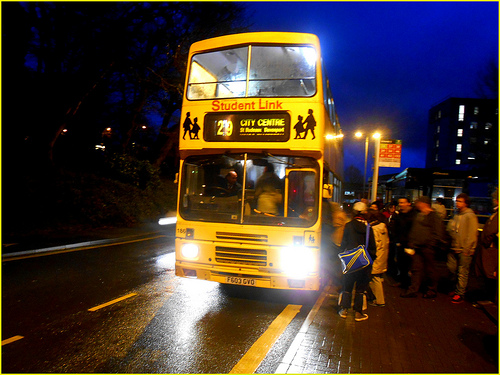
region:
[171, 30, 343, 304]
yellow double decker bus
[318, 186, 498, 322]
people boarding the bus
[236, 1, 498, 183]
dark blue twilight sky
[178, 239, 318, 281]
headlights on front of bus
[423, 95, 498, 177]
tall building in background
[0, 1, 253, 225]
trees on side of road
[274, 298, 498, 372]
brick sidewalk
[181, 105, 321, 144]
pictures of people on front of bus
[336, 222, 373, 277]
a blue bag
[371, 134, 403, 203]
sign at bus stop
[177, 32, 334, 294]
bus is a double decker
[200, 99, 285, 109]
bus has writing on it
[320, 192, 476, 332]
people waiting to get on bus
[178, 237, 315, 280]
lights on the bus are on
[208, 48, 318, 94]
lights inside bus are on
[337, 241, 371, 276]
person is wearing a bag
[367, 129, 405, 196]
sign next to people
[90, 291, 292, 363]
street has yellow lines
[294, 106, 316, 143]
picture of people on the bus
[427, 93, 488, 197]
buildings in the background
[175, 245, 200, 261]
a headlight of a bus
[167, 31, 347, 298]
a tall yellow bus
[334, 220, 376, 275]
a blue and yellow bag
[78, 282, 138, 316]
a long yellow street marking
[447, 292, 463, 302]
a man's black and red tennis shoe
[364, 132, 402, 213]
a colorful street sign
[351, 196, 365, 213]
a white baseball cap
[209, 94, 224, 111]
a red capital letter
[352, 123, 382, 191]
a tall lamp pole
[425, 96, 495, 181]
a tall building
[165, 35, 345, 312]
a yellow double decker bus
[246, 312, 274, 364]
a yellow line on the street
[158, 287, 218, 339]
light reflecting on the street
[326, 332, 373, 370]
brown bricks in the sidewalk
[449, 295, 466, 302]
red laces on a shoe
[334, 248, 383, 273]
a blue bag with a silver stripe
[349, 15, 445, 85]
the dark blue night sky overhead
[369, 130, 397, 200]
a sign on a metal pole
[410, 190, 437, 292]
a man wearing a dark green hat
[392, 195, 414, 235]
a man wearing a black shirt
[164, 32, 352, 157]
Top level of a double-decker bus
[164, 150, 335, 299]
Bottom level of the double-decker bus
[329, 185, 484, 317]
Passengers waiting to board the bus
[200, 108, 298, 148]
Electric sign on a passenger bus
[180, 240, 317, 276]
Headlights on a passenger bus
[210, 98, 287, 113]
Company logo on a passenger bus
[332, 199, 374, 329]
Pedestrian carrying bookbag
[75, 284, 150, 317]
Dotted yellow lines painted in the street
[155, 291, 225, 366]
Wet surface of the road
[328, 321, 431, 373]
Sidewalk made with bricks